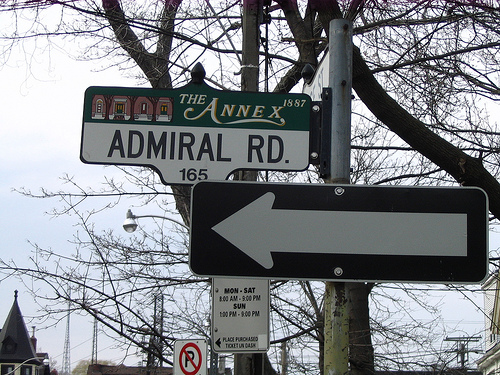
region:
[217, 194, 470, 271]
a large white arrow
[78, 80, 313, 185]
a street sign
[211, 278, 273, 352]
a sign about parking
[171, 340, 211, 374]
a sign indicating no parking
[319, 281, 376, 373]
the trunk of a tree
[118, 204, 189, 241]
a light post for the sidewalk and road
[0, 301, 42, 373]
the pointy top of a building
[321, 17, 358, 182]
a gray metal pole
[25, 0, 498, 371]
the branches of the trees behind the street signs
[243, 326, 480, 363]
telephone cables stretching across the street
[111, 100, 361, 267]
Road signage in the photo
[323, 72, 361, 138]
A metal pole in the photo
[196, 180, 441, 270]
Signage giving directions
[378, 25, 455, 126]
Trees in the photo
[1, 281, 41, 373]
A church at the back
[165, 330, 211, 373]
A sign showing no parking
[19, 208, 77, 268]
Clouds in the skies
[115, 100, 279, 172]
Text on the signage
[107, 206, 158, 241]
A lamp on the street light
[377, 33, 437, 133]
Branches of a tree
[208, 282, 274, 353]
white sign on pole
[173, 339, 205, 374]
white sign on pole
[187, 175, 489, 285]
black sign on pole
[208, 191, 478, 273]
white arrow on sign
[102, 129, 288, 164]
black writing on sign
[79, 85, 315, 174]
white sign on pole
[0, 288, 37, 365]
black roof of building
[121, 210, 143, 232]
metal light hanging from pole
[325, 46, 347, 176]
metal pole with sign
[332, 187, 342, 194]
metal bolt of sign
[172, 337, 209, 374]
a no parking sign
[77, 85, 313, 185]
a green and white street sign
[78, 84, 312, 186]
Admiral Rd. street sign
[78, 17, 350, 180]
a street sign bolted to a metal pole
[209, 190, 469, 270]
an white arrow on a black sign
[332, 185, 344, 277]
two metal bolts in the sign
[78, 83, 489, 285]
two signs on a metal pole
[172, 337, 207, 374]
a white no parking sign on a pole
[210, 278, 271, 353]
a sign under a black and white sign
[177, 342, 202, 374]
a no parking symbol on a white sign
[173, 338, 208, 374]
White no parking sign.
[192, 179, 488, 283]
Black sign with white arrow.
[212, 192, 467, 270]
White arrow on a sign.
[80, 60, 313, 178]
Green and white Admiral Rd. sign.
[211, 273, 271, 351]
White sign with hours listed on it.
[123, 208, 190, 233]
Street lamp is off in the daytime.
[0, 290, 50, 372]
White house with a black roof.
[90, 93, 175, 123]
House graphics on street sign.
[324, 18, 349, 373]
Pole holding up one way and street sign.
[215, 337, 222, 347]
Black arrow on hours sign.